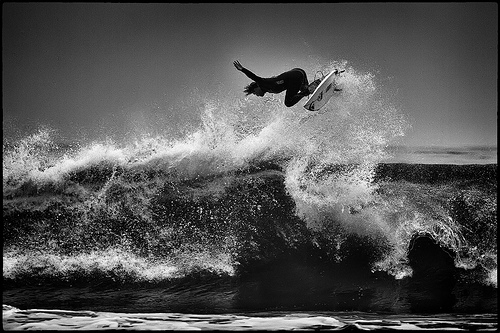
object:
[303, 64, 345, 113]
surfboard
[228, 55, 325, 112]
person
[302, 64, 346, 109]
shortboard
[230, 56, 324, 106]
person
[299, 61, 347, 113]
surfboard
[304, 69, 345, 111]
surfboard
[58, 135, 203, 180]
waves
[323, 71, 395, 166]
splash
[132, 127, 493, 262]
wave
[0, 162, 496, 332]
water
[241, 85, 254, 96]
hair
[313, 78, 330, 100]
surfboard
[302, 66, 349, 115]
surfboard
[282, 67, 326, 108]
legs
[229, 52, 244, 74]
hand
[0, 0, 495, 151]
sky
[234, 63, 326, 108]
man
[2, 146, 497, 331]
ocean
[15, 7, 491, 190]
sky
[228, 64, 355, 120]
man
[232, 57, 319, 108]
person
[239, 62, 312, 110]
wetsuit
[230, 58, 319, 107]
surfer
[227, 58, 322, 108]
man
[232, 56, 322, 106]
man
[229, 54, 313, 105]
person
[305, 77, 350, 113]
surfboard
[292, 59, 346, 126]
surfboard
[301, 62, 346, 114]
fins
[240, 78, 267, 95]
hair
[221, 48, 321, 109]
man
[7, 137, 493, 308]
wave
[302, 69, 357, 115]
surfboard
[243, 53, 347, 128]
man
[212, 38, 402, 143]
surfer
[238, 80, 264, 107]
hair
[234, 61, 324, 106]
person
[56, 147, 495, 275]
wave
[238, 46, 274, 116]
head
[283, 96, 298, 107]
knee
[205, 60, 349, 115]
person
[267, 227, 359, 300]
water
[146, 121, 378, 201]
foam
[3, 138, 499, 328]
wave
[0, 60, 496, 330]
water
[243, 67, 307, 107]
wet suit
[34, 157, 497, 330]
seawater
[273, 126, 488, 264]
wave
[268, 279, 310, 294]
water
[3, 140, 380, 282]
wave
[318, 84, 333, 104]
black symbols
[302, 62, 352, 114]
surfboard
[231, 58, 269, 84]
arm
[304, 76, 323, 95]
foot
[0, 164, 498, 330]
ocean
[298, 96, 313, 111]
pony tip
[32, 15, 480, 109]
air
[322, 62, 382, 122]
fins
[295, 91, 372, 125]
logo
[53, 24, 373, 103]
air